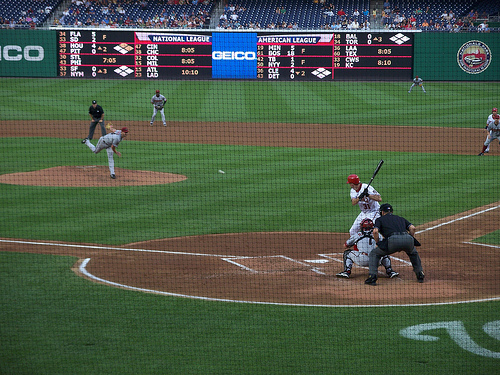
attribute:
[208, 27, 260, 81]
advertisement — Geico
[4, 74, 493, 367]
field — baseball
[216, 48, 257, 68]
sign — blue, Geico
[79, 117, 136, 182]
pitcher — throwing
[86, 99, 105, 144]
umpire — watching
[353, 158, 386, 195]
bat — black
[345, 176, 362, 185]
helmet — red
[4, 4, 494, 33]
people — sitting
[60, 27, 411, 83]
board — black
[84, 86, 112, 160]
man — wearing, holding, bent, kneeling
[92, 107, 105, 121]
shirt — black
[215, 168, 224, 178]
ball — moving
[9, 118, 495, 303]
dirt — brown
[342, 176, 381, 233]
player — holding, grey, playing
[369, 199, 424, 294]
umpire — leaning